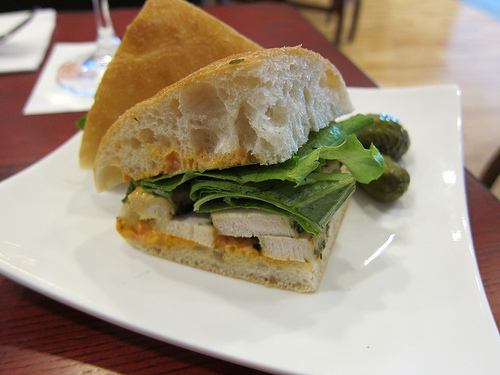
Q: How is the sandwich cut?
A: In half.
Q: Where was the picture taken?
A: A restaurant.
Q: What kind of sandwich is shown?
A: A chicken sandwich.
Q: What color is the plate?
A: White.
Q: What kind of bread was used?
A: French bread.